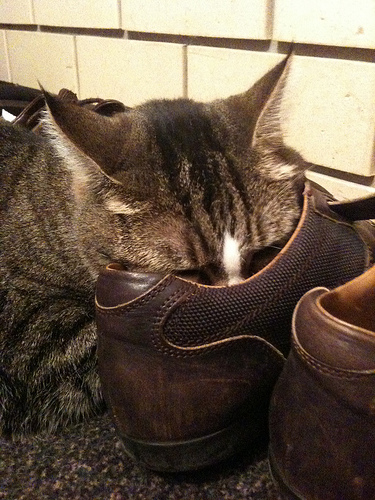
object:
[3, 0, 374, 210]
wall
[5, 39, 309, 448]
cat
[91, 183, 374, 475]
shoe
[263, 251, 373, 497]
shoe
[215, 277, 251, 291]
nose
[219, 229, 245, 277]
mark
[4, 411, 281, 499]
rug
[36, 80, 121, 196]
ear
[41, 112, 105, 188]
hair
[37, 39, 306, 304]
head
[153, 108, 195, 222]
stripe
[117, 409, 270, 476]
sole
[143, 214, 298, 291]
face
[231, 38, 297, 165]
ear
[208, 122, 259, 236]
stripe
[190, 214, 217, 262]
stripe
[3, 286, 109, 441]
arm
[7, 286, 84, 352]
stripe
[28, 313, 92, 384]
stripe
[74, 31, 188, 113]
tile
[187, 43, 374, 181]
tile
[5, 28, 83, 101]
tile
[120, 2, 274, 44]
tile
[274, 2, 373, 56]
tile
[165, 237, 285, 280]
eyes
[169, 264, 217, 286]
eye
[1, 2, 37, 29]
block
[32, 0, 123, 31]
block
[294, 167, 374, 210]
block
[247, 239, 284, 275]
eye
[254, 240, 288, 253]
eyebrow whisker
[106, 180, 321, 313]
collar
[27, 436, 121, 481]
yarns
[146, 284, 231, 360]
seam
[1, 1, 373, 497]
room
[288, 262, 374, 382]
top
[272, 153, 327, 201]
eyebrow whisker